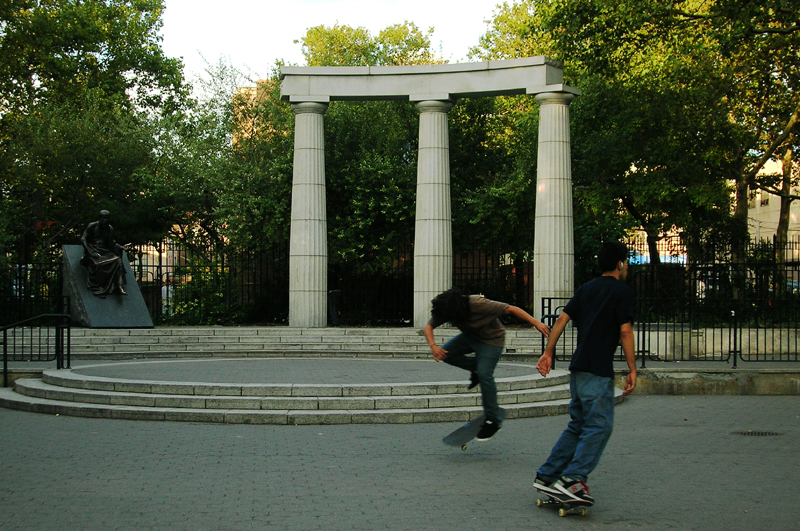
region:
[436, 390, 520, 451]
Silver skateboard in the air.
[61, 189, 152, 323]
Statute on the side of the monument.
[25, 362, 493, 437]
Circle of steps on the concrete.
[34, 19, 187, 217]
Group of trees to the left.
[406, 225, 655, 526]
Two boys on the skateboards.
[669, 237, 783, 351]
Black fence behind the monument.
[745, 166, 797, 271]
Small grey building in the back.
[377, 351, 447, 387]
Wet spot on the ground.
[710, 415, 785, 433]
Hole to the sewage system on the ground.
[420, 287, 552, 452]
boy doing a jump on a skateboard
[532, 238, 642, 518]
boy is on a skateboard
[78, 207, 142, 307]
decorative statue of a person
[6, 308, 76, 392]
black hand rail leading up steps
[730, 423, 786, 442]
manhole cover on the ground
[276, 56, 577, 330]
three white decorative pillars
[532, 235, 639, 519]
skateboarder is leaning forward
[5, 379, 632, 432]
rounded cement steps at a park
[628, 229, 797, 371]
black metal fence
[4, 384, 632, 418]
a step on a stairway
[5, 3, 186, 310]
a tree in a city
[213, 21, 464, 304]
a tree in a city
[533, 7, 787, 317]
a tree in a city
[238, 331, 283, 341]
a brick in a wall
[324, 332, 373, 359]
a brick in a wall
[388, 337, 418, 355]
a brick in a wall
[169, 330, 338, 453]
a view of steps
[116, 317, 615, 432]
a view of stage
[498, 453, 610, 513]
shoes of the perosn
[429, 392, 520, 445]
skate machine in air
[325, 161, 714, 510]
two man playing with skate boards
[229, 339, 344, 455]
steps near the stage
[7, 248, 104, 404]
a view of gate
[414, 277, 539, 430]
skater wearing brown shirt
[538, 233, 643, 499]
skater wearing black shirt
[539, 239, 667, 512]
man riding a skateboard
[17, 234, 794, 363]
black railings around the park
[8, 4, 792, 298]
trees behind the black railing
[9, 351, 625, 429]
stone steps in the park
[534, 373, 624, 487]
jeans the man in a black shirt is wearing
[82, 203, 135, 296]
statue of a man on the left side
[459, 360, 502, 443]
black and white shoes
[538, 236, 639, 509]
man on a skateboard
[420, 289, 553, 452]
man with foot off skateboard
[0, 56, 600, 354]
columns on top of steps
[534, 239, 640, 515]
man wearing an ear piece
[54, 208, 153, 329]
statue sitting on a incline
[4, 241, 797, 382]
fence made out of metal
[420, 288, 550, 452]
man wearing brown shirt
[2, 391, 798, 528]
skateboard is off the ground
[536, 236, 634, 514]
man wearing black shirt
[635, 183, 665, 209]
green leaves on the tree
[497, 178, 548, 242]
green leaves on the tree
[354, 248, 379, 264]
green leaves on the tree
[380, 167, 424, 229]
green leaves on the tree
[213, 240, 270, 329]
green leaves on the tree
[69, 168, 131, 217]
green leaves on the tree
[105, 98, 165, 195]
green leaves on the tree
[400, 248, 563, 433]
boy jumping on skateboard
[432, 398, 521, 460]
skateboard in air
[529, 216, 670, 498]
boy in black shirt riding skateboard